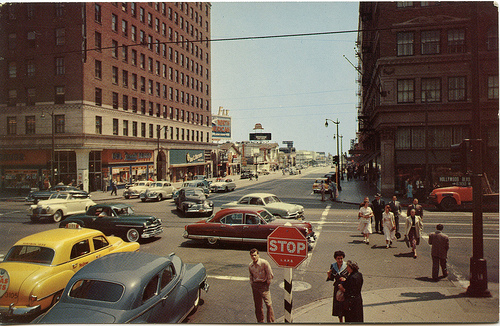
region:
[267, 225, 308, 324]
a red and white stop sign on a pole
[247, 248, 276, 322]
a man wearing a tan shirt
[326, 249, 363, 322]
two women talking on the street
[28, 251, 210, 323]
a grey car on the street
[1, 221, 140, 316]
a yellow taxi cab on the street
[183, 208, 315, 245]
a red car on the street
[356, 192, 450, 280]
a group of people crossing the street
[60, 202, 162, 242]
a green car on the street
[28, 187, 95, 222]
a white car on the street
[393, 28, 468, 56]
three windows in a building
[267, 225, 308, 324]
stop sign on the roadside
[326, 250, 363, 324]
two women talking on the sidewalk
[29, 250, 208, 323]
light blue car in driving in the road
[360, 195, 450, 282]
group of people crossing the street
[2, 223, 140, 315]
yellow taxi cab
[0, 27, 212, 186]
tall red brick building on the corner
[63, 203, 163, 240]
dark green car on the road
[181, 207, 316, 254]
red car on the road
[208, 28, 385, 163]
blue sky above the street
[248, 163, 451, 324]
group of people along a sidewalk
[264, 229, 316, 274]
red hexagon traffic sign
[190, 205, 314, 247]
vehicle driving through intersection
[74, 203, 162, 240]
vehicle driving through intersection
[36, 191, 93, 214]
vehicle driving through intersection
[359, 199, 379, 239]
woman wearing white dress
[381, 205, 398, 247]
woman wearing white dress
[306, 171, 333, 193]
vehicle parked on side of street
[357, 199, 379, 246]
woman walking across the street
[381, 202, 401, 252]
woman walking across the steet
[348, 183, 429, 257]
people walking across the street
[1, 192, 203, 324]
vehicles in the street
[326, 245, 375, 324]
people standing on street corner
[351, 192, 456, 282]
people crossing the street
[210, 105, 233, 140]
billboard behind a building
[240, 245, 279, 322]
man standing on street corner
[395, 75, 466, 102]
windows on a building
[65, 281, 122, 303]
window in a vehicle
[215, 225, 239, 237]
door of a vehicle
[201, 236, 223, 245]
tire of a vehicle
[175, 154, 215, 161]
lettering on the building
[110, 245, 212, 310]
car on a street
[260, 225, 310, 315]
sign on a street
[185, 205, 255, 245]
car on a street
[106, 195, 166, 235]
car on a street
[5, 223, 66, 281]
taxi on a street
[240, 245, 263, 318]
man wearing a pink shirt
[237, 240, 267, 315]
man standing on a street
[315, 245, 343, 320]
woman wearing a dress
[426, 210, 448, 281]
man wearing a suit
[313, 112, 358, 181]
light on a pole